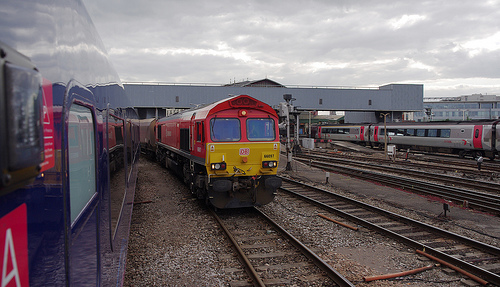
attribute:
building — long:
[129, 74, 444, 132]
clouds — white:
[145, 7, 469, 79]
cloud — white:
[113, 51, 252, 83]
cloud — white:
[92, 3, 257, 47]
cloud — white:
[274, 55, 435, 87]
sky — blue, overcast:
[84, 2, 499, 98]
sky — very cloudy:
[6, 3, 496, 120]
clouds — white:
[1, 0, 498, 92]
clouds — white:
[334, 11, 488, 69]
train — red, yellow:
[141, 94, 282, 210]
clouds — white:
[104, 0, 494, 83]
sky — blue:
[124, 2, 499, 71]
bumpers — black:
[207, 172, 282, 212]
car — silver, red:
[368, 119, 495, 154]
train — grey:
[319, 117, 496, 151]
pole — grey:
[280, 99, 295, 171]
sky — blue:
[243, 7, 405, 68]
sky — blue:
[90, 56, 216, 117]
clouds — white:
[78, 49, 133, 112]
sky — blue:
[84, 49, 140, 119]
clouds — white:
[75, 52, 147, 118]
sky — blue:
[79, 49, 149, 76]